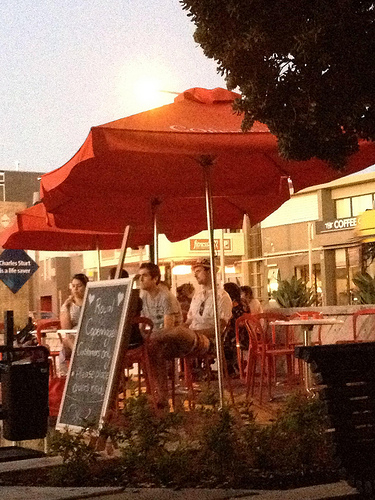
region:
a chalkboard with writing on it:
[58, 278, 139, 444]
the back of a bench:
[279, 333, 374, 496]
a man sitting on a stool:
[162, 249, 232, 360]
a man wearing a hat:
[186, 253, 224, 286]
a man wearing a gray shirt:
[125, 260, 184, 334]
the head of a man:
[133, 259, 161, 290]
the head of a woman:
[65, 266, 92, 301]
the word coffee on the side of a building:
[327, 212, 360, 231]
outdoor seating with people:
[29, 260, 368, 382]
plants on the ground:
[49, 395, 349, 476]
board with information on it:
[49, 275, 134, 429]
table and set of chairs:
[237, 301, 373, 391]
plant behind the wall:
[268, 264, 310, 309]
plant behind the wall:
[344, 250, 374, 303]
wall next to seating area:
[264, 298, 373, 361]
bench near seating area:
[299, 340, 374, 469]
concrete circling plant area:
[1, 449, 344, 498]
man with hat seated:
[170, 252, 234, 358]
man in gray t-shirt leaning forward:
[130, 257, 184, 325]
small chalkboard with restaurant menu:
[53, 278, 139, 440]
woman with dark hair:
[53, 267, 102, 356]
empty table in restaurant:
[236, 304, 369, 403]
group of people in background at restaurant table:
[175, 276, 264, 327]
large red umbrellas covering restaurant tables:
[0, 77, 373, 255]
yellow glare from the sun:
[104, 41, 185, 117]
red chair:
[236, 305, 311, 415]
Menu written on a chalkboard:
[51, 272, 133, 439]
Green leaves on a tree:
[171, 0, 369, 174]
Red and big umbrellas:
[0, 77, 368, 400]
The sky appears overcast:
[0, 0, 240, 167]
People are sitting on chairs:
[51, 258, 264, 408]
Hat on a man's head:
[180, 251, 225, 287]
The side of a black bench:
[285, 332, 369, 497]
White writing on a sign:
[0, 243, 45, 294]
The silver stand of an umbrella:
[195, 161, 230, 405]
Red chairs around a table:
[231, 302, 371, 404]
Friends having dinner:
[52, 252, 270, 408]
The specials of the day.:
[45, 278, 143, 444]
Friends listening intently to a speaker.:
[34, 243, 262, 403]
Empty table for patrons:
[222, 289, 374, 391]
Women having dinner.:
[164, 260, 268, 361]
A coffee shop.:
[274, 209, 374, 301]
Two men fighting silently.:
[123, 244, 254, 385]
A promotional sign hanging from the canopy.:
[1, 227, 46, 307]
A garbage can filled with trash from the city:
[7, 303, 66, 448]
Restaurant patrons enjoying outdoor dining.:
[3, 77, 281, 378]